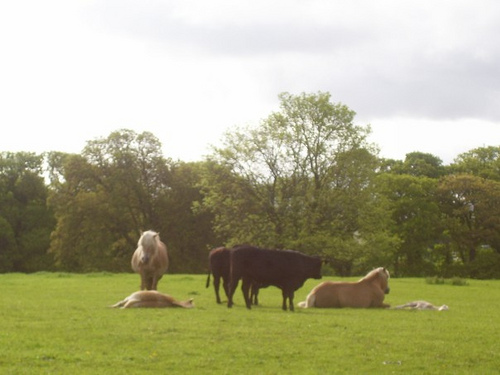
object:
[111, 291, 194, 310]
horse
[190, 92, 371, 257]
tree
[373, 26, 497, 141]
sky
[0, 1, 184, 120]
clouds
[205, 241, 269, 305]
cow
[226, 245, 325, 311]
cow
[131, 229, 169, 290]
horse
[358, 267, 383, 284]
mane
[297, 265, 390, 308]
animals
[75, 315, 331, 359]
grass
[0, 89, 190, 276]
trees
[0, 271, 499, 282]
edge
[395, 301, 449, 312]
horse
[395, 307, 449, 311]
side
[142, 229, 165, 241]
mane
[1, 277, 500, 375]
field